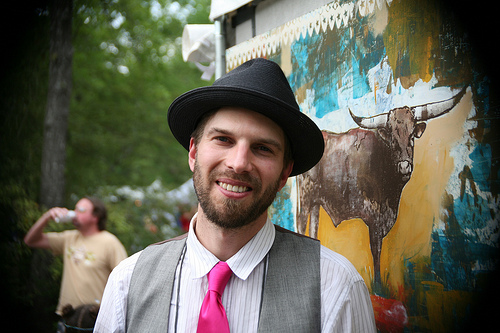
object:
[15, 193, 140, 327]
man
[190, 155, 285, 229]
beard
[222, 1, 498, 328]
wall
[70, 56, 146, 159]
leaves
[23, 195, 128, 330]
background person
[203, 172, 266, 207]
smile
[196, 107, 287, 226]
face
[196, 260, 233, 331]
pinktie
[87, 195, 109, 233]
hair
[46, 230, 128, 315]
shirt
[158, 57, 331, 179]
hat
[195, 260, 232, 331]
tie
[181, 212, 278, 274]
collar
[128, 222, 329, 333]
gray vest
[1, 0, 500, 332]
background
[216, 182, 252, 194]
teeth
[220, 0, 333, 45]
section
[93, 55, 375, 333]
man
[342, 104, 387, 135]
horn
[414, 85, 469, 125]
horn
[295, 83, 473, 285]
bull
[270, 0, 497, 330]
painting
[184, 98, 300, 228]
head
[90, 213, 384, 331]
shirt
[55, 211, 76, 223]
can